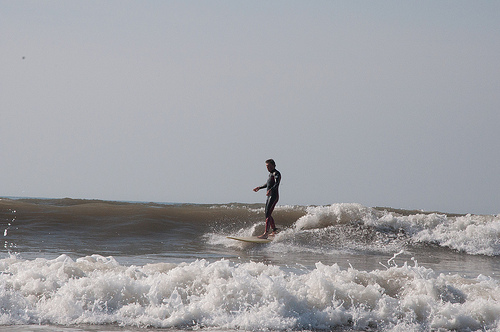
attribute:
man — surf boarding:
[251, 155, 286, 239]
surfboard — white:
[221, 224, 297, 252]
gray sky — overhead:
[112, 27, 262, 107]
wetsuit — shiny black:
[259, 176, 282, 226]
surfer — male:
[255, 159, 290, 204]